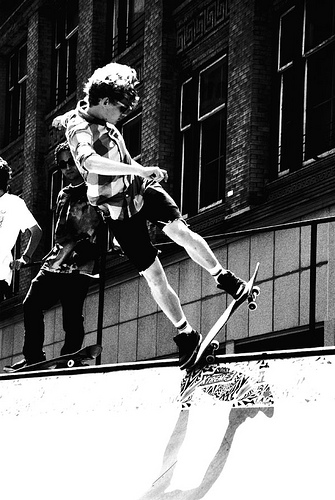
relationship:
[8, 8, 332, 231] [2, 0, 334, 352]
wall on building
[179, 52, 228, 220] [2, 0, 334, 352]
window on building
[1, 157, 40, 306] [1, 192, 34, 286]
man wearing t-shirt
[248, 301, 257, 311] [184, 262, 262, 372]
wheel on skateboard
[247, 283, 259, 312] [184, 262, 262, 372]
wheels on front skateboard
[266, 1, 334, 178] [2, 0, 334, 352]
window on side of a building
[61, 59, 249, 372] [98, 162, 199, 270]
men with shorts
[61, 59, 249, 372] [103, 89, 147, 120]
men with glasses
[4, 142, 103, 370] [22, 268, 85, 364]
skateboarder with pants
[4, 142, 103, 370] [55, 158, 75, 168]
skateboarder with sunglasses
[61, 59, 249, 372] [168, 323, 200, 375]
men wearing skating shoe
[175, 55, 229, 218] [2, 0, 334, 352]
window on side building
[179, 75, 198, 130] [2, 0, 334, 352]
window on side of building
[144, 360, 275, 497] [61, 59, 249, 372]
shadow of men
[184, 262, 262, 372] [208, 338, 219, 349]
skateboard with wheels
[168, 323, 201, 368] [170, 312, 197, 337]
skating shoe with sock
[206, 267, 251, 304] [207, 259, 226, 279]
shoe with sock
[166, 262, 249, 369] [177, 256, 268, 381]
feet on skateboard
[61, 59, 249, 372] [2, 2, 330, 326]
men in park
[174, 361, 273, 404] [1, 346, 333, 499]
print on skate wall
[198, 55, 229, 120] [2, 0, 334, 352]
window on building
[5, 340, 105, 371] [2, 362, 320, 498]
skateboard being ridden ramp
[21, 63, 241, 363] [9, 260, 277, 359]
men on skateboards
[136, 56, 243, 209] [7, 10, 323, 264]
windows on a building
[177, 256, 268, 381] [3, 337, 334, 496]
skateboard on ramp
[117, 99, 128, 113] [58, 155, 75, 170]
sunglasses on sunglasses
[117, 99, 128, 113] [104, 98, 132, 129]
sunglasses on man's face